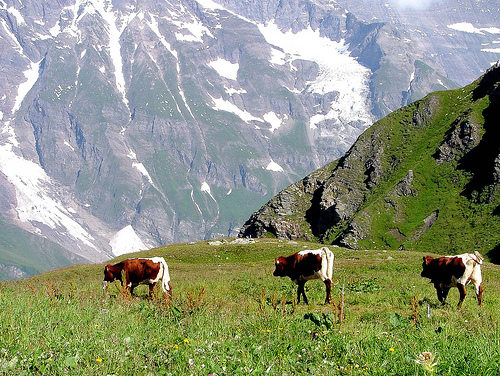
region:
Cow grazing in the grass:
[89, 253, 208, 298]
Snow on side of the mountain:
[285, 28, 458, 185]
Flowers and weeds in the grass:
[111, 315, 201, 369]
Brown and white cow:
[262, 236, 348, 328]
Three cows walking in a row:
[82, 232, 499, 331]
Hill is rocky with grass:
[362, 125, 484, 257]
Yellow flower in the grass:
[179, 332, 191, 346]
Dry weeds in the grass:
[184, 285, 218, 316]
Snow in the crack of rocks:
[260, 16, 436, 143]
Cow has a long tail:
[464, 240, 498, 267]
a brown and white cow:
[91, 249, 181, 304]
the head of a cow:
[100, 257, 117, 289]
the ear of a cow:
[273, 252, 283, 267]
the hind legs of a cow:
[318, 272, 338, 309]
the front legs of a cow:
[290, 275, 314, 307]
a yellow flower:
[180, 331, 193, 348]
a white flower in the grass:
[186, 352, 198, 369]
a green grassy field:
[2, 236, 499, 374]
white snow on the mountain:
[256, 17, 371, 132]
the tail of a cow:
[320, 245, 334, 280]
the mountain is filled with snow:
[97, 45, 287, 132]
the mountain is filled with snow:
[75, 16, 402, 236]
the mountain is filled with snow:
[125, 70, 465, 330]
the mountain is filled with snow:
[112, 30, 432, 140]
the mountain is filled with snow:
[136, 87, 293, 162]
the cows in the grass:
[101, 247, 487, 310]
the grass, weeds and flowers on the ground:
[28, 293, 466, 373]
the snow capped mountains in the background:
[11, 5, 266, 203]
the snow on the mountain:
[285, 32, 333, 59]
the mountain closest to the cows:
[353, 117, 498, 247]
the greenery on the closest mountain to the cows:
[411, 155, 477, 237]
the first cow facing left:
[102, 257, 174, 300]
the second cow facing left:
[273, 247, 332, 302]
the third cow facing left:
[420, 249, 482, 309]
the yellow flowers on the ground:
[256, 324, 286, 340]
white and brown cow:
[271, 249, 353, 310]